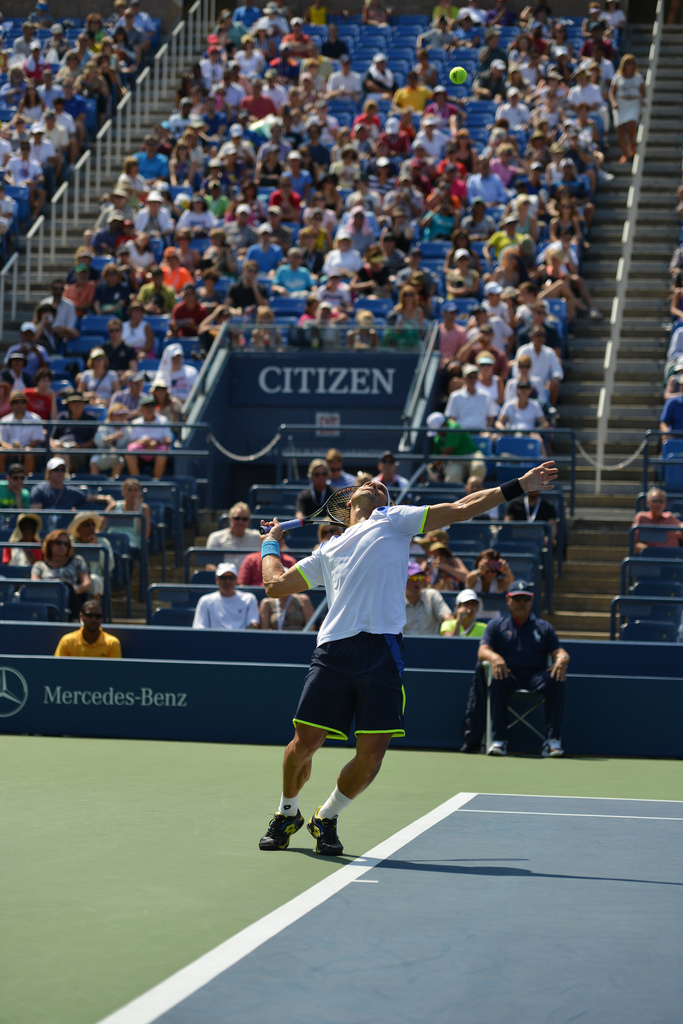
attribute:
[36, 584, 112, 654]
shirt — yellow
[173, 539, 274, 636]
shirt — white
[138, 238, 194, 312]
shirt — orange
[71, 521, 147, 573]
shirt — white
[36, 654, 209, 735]
wall — blue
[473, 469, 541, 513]
band — black, thick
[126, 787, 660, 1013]
line — white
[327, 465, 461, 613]
man — athlete, tennis player, young, healthy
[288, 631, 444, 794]
pants — blue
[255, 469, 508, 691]
shirt — white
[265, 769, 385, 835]
socks — clean, soft, white, decorated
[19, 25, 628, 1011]
sunny — day, area, sky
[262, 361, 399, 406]
writing — white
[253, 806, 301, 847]
shoes — black, yellow, sneakers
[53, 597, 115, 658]
shirt — yellow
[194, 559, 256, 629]
shirt — white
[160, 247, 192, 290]
shirt — orange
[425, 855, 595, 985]
surface — bluish, grey, clay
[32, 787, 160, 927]
surface — clay, green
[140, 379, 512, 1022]
person — athlete, male, tennis player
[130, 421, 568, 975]
person — tennis player, athlete, male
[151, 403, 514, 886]
person — male, athlete, tennis player, healthy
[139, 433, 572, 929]
person — healthy, male, athlete, tennis player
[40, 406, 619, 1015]
court — large, tennis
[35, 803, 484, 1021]
line — white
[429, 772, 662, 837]
line — white